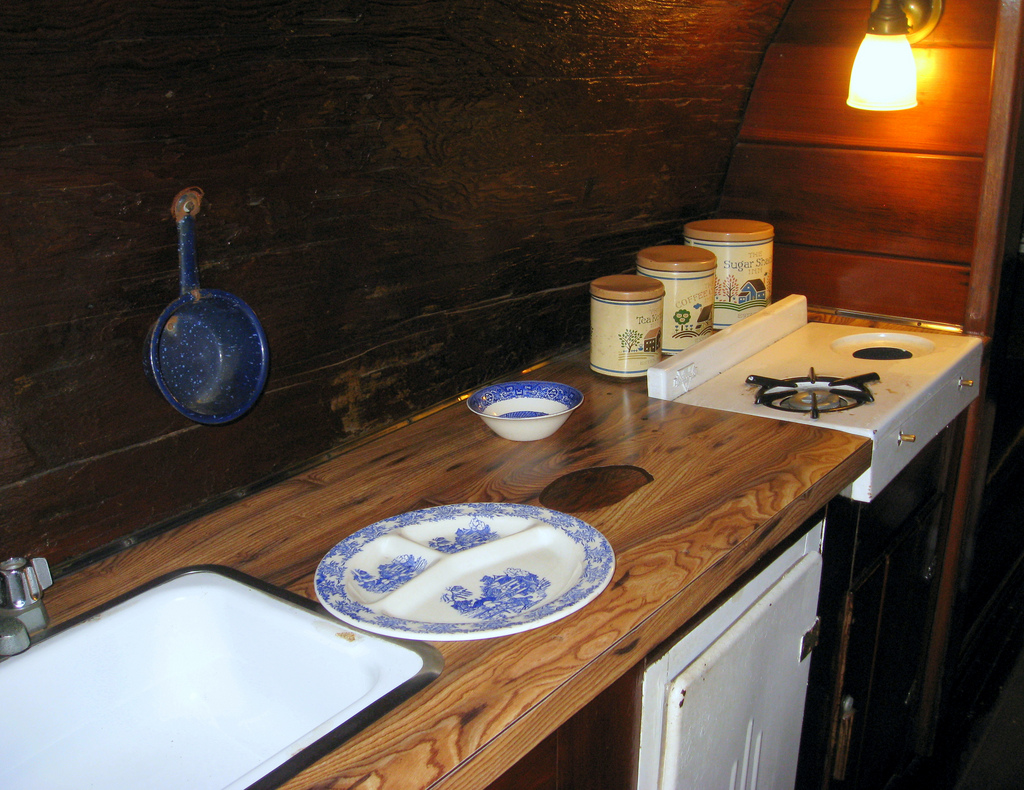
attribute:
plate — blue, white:
[305, 501, 619, 648]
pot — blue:
[150, 181, 268, 420]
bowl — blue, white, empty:
[472, 381, 580, 440]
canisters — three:
[589, 198, 771, 375]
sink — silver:
[5, 538, 436, 786]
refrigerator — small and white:
[646, 504, 818, 789]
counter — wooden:
[1, 371, 872, 779]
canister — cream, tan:
[592, 273, 665, 376]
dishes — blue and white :
[314, 378, 622, 638]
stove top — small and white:
[782, 297, 925, 486]